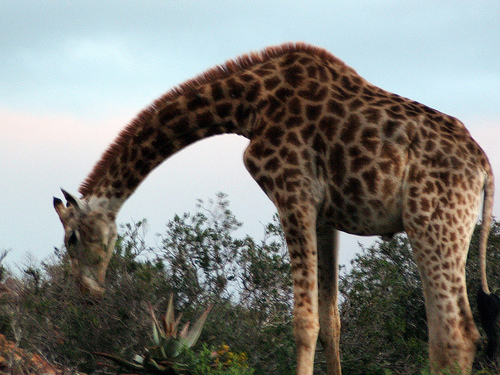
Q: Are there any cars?
A: No, there are no cars.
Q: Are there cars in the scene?
A: No, there are no cars.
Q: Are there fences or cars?
A: No, there are no cars or fences.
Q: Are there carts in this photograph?
A: No, there are no carts.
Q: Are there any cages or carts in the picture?
A: No, there are no carts or cages.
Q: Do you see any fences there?
A: No, there are no fences.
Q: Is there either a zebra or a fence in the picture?
A: No, there are no fences or zebras.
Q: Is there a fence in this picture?
A: No, there are no fences.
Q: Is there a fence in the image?
A: No, there are no fences.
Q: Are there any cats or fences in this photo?
A: No, there are no fences or cats.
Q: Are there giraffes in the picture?
A: Yes, there is a giraffe.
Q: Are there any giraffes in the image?
A: Yes, there is a giraffe.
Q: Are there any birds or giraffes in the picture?
A: Yes, there is a giraffe.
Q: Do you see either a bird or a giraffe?
A: Yes, there is a giraffe.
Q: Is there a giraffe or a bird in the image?
A: Yes, there is a giraffe.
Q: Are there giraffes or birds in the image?
A: Yes, there is a giraffe.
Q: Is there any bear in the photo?
A: No, there are no bears.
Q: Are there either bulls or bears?
A: No, there are no bears or bulls.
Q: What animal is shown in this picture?
A: The animal is a giraffe.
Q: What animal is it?
A: The animal is a giraffe.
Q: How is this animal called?
A: This is a giraffe.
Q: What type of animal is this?
A: This is a giraffe.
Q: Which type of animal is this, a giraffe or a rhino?
A: This is a giraffe.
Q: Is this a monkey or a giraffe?
A: This is a giraffe.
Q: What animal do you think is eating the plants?
A: The giraffe is eating the plants.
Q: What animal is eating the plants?
A: The animal is a giraffe.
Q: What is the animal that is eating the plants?
A: The animal is a giraffe.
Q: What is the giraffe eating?
A: The giraffe is eating plants.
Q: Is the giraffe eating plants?
A: Yes, the giraffe is eating plants.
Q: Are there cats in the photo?
A: No, there are no cats.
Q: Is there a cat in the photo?
A: No, there are no cats.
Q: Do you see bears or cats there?
A: No, there are no cats or bears.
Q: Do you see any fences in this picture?
A: No, there are no fences.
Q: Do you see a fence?
A: No, there are no fences.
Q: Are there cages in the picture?
A: No, there are no cages.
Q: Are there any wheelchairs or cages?
A: No, there are no cages or wheelchairs.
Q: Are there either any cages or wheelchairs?
A: No, there are no cages or wheelchairs.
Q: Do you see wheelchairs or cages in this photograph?
A: No, there are no cages or wheelchairs.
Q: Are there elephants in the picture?
A: No, there are no elephants.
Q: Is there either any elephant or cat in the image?
A: No, there are no elephants or cats.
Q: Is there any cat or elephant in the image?
A: No, there are no elephants or cats.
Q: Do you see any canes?
A: No, there are no canes.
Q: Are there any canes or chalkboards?
A: No, there are no canes or chalkboards.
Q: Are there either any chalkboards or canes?
A: No, there are no canes or chalkboards.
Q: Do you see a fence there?
A: No, there are no fences.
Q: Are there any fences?
A: No, there are no fences.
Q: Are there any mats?
A: No, there are no mats.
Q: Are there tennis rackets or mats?
A: No, there are no mats or tennis rackets.